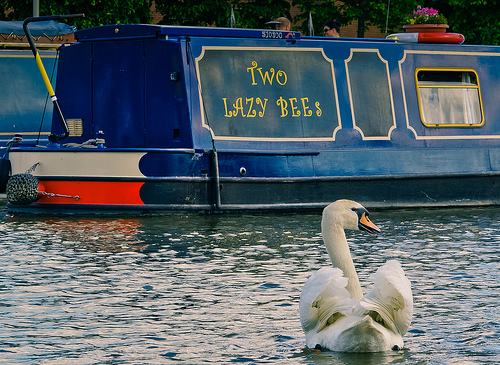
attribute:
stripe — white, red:
[6, 150, 148, 181]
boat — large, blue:
[6, 14, 499, 212]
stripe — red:
[39, 181, 145, 206]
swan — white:
[298, 197, 413, 353]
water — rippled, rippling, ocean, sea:
[0, 208, 499, 364]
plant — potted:
[402, 4, 450, 34]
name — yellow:
[218, 60, 324, 119]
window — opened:
[413, 68, 487, 128]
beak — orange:
[359, 214, 383, 236]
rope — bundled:
[4, 172, 40, 207]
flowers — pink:
[410, 5, 439, 19]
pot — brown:
[403, 25, 451, 33]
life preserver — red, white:
[382, 32, 466, 43]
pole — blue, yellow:
[21, 11, 87, 141]